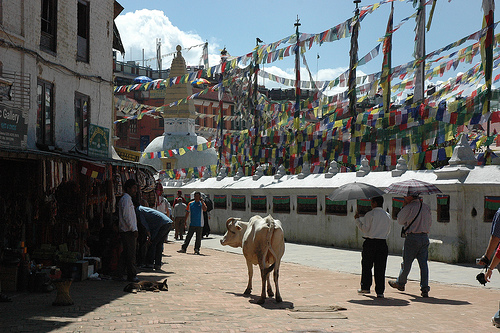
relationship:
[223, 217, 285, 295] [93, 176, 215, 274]
cow looking at people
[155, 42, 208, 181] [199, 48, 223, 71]
statue in background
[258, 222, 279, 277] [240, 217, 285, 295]
tail of cow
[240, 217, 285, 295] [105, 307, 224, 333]
cow standing on ground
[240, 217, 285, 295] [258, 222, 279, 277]
cow has a tail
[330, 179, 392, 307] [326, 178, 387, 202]
man walking with umbrella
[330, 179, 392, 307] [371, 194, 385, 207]
man has a head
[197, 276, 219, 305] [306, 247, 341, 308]
middle of road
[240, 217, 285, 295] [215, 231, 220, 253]
cow looking to left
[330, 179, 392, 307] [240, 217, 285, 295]
man looking at cow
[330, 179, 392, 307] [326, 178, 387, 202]
man carrying umbrella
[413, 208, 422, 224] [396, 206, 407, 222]
strap over shoulder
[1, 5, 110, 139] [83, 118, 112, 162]
building has a sign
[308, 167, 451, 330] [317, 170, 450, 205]
men with umbrellas